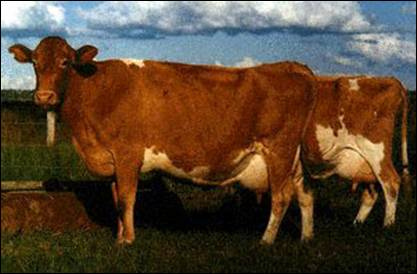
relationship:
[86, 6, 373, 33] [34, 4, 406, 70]
clouds in sky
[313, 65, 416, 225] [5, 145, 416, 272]
cow in pasture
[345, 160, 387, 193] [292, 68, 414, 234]
utters on cow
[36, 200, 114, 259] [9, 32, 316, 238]
grass under cow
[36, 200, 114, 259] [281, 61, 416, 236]
grass under cow